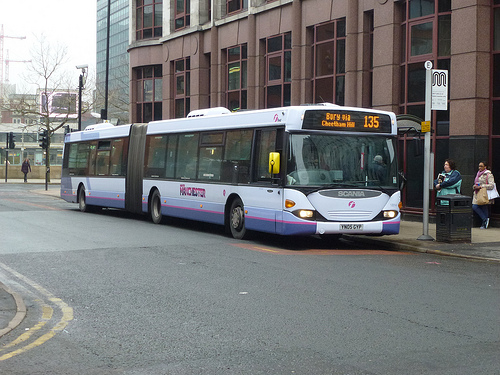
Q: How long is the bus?
A: Twice as long.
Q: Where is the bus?
A: Street.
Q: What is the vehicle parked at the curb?
A: Bus.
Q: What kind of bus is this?
A: Double bus.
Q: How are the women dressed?
A: In coats.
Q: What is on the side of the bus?
A: Advertisement.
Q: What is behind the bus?
A: Red brick building.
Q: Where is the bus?
A: At a bus stop.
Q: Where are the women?
A: On the sidewalk.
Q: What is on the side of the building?
A: Windows.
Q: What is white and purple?
A: Bus.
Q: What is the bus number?
A: 135.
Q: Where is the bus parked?
A: Bus stop.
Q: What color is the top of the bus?
A: White.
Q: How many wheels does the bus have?
A: Six.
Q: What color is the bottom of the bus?
A: Blue.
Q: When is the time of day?
A: Daytime.